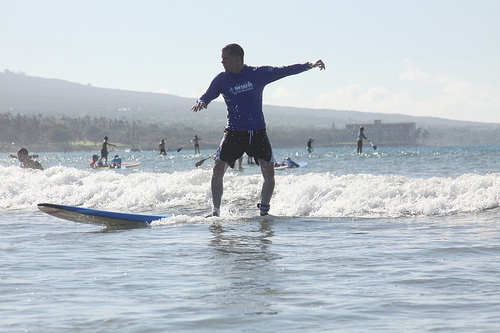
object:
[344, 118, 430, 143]
building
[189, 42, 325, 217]
man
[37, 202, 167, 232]
surfboard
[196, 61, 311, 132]
shirt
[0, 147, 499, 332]
water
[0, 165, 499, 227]
wave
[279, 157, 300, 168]
person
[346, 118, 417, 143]
wall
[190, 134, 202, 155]
person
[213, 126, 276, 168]
shorts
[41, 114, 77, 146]
tree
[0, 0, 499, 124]
sky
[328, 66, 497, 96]
cloud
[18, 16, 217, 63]
cloud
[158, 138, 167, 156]
person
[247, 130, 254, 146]
tie string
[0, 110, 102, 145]
woods